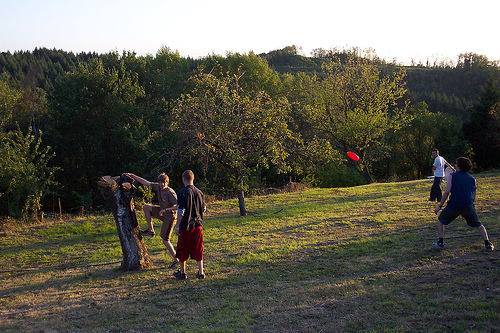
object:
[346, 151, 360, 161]
frisbee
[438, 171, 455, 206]
arm extension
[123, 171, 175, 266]
wrong position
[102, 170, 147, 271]
tree stump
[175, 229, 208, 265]
shorts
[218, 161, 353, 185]
hedges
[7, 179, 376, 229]
border field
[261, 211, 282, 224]
grass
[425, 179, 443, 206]
pants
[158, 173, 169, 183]
hair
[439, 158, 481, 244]
boys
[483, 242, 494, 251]
sneaker feet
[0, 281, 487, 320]
field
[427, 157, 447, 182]
shirt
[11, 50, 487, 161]
hill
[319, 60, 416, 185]
trees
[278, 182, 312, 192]
pile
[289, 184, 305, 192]
dirt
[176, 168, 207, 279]
men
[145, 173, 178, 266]
guys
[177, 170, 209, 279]
each other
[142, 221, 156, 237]
foot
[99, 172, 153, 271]
treebark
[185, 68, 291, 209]
tree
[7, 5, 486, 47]
sky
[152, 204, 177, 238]
shorts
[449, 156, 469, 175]
top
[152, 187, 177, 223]
shirt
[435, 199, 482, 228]
shorts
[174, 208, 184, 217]
undershirt